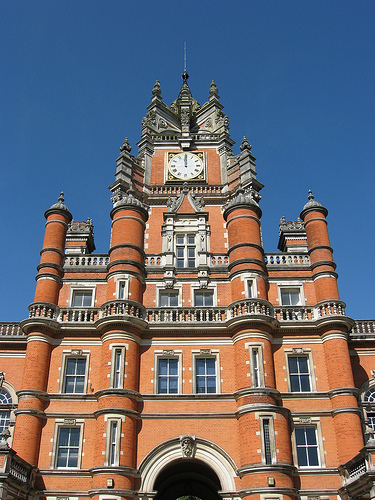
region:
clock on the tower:
[163, 150, 208, 178]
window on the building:
[286, 424, 328, 473]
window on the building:
[47, 409, 84, 467]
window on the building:
[188, 353, 222, 399]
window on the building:
[157, 355, 184, 394]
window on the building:
[64, 351, 90, 394]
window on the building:
[284, 283, 310, 321]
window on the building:
[293, 357, 317, 399]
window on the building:
[191, 356, 210, 394]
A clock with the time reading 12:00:
[164, 151, 205, 183]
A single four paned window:
[289, 420, 324, 471]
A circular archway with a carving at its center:
[133, 436, 241, 494]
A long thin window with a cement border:
[256, 411, 281, 468]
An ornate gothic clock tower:
[115, 44, 263, 209]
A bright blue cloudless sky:
[341, 178, 373, 270]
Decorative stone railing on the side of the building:
[24, 300, 357, 329]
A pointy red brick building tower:
[296, 186, 337, 251]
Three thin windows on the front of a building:
[105, 270, 127, 474]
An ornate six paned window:
[159, 187, 209, 290]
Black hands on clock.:
[176, 146, 195, 171]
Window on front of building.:
[289, 417, 326, 483]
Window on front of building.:
[284, 352, 330, 405]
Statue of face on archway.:
[174, 435, 202, 461]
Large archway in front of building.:
[128, 437, 240, 488]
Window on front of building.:
[49, 423, 90, 466]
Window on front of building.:
[57, 350, 107, 402]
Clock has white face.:
[169, 153, 215, 177]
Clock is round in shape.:
[165, 149, 216, 187]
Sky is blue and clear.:
[30, 24, 116, 96]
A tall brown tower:
[54, 39, 366, 388]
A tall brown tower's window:
[157, 347, 179, 397]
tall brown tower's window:
[194, 346, 220, 399]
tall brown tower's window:
[295, 419, 323, 469]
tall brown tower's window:
[286, 342, 308, 391]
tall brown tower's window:
[53, 342, 103, 390]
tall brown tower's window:
[44, 419, 85, 474]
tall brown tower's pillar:
[295, 189, 360, 467]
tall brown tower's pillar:
[228, 189, 296, 485]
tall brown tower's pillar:
[105, 197, 145, 496]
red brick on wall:
[218, 422, 248, 444]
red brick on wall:
[320, 420, 347, 450]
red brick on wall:
[325, 396, 340, 407]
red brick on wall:
[218, 363, 233, 371]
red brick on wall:
[90, 395, 105, 403]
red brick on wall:
[25, 341, 43, 358]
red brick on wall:
[0, 356, 16, 375]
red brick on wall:
[19, 425, 27, 440]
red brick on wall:
[48, 472, 78, 481]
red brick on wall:
[87, 341, 112, 357]